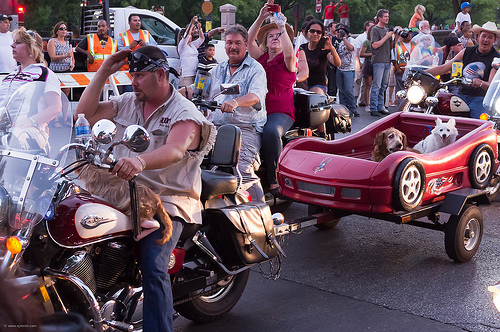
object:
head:
[374, 126, 410, 153]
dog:
[368, 126, 420, 161]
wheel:
[395, 155, 428, 211]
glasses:
[123, 48, 163, 68]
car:
[276, 109, 497, 222]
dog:
[419, 115, 465, 153]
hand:
[219, 99, 238, 114]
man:
[203, 24, 271, 197]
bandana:
[128, 57, 181, 79]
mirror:
[122, 124, 153, 154]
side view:
[0, 0, 67, 69]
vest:
[86, 33, 119, 72]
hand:
[102, 47, 133, 73]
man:
[81, 18, 121, 74]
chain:
[258, 258, 284, 283]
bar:
[282, 212, 329, 233]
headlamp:
[3, 233, 30, 257]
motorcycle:
[0, 118, 281, 321]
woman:
[251, 19, 301, 182]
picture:
[0, 0, 500, 332]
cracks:
[295, 284, 363, 305]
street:
[379, 262, 492, 324]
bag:
[202, 200, 286, 268]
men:
[121, 13, 160, 67]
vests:
[118, 29, 153, 69]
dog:
[76, 144, 174, 244]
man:
[74, 40, 194, 332]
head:
[123, 43, 174, 105]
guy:
[449, 20, 498, 117]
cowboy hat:
[470, 20, 499, 34]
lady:
[295, 20, 341, 92]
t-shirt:
[295, 42, 333, 88]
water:
[71, 111, 91, 154]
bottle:
[74, 113, 93, 144]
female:
[0, 23, 57, 90]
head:
[9, 29, 42, 64]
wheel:
[443, 200, 487, 264]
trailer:
[275, 109, 499, 261]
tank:
[51, 192, 132, 243]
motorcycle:
[174, 89, 333, 209]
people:
[299, 20, 345, 101]